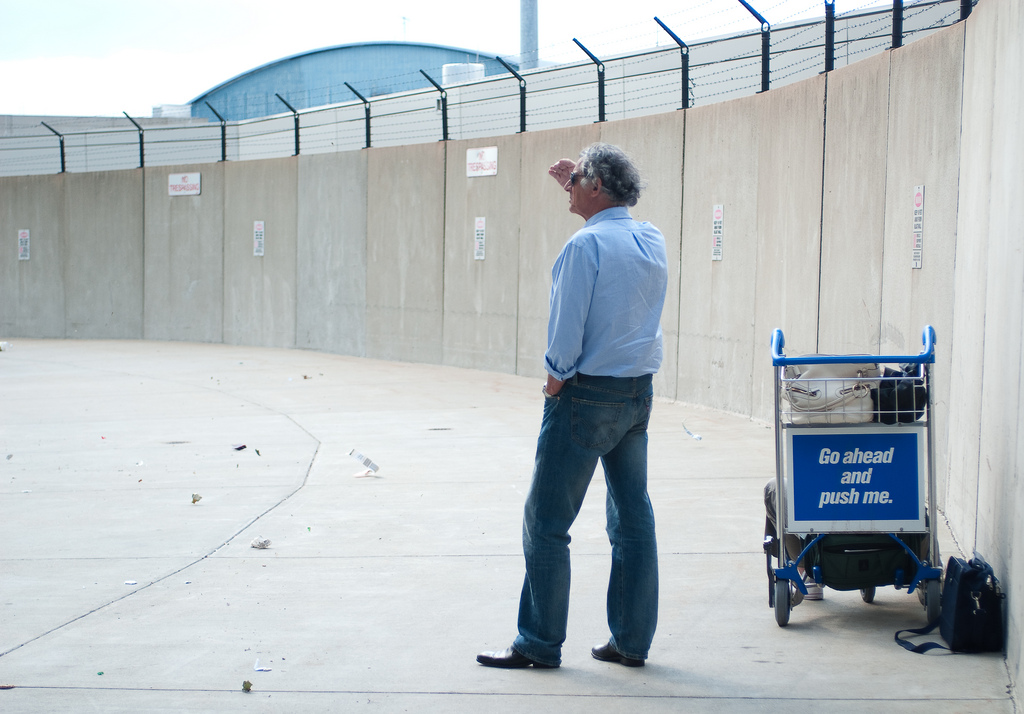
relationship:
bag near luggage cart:
[894, 541, 1003, 663] [758, 313, 954, 647]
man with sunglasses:
[469, 146, 667, 684] [562, 162, 592, 188]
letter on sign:
[816, 443, 835, 470] [777, 417, 926, 532]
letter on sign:
[818, 447, 895, 507] [771, 414, 923, 528]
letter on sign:
[818, 447, 895, 507] [777, 414, 936, 529]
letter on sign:
[818, 447, 895, 507] [769, 415, 928, 536]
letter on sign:
[818, 447, 895, 507] [777, 417, 926, 532]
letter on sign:
[818, 447, 895, 507] [792, 431, 926, 522]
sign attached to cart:
[777, 417, 926, 532] [766, 325, 939, 423]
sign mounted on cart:
[777, 417, 926, 532] [766, 325, 939, 423]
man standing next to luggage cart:
[469, 146, 667, 684] [762, 324, 949, 635]